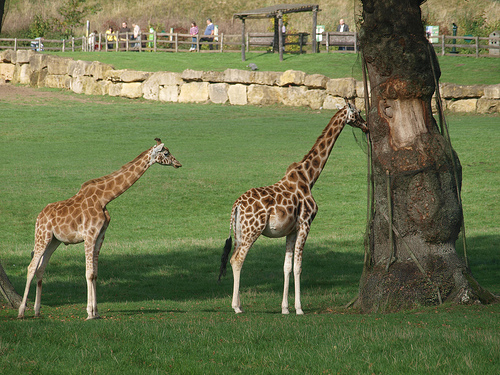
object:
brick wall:
[251, 74, 333, 100]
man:
[336, 19, 349, 51]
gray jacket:
[336, 24, 348, 32]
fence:
[0, 28, 497, 58]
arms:
[83, 242, 95, 313]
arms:
[93, 235, 105, 313]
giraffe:
[15, 137, 183, 321]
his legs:
[20, 247, 47, 303]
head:
[154, 137, 182, 169]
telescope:
[450, 23, 460, 54]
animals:
[216, 97, 370, 315]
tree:
[333, 0, 497, 313]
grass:
[139, 55, 217, 68]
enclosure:
[0, 82, 500, 375]